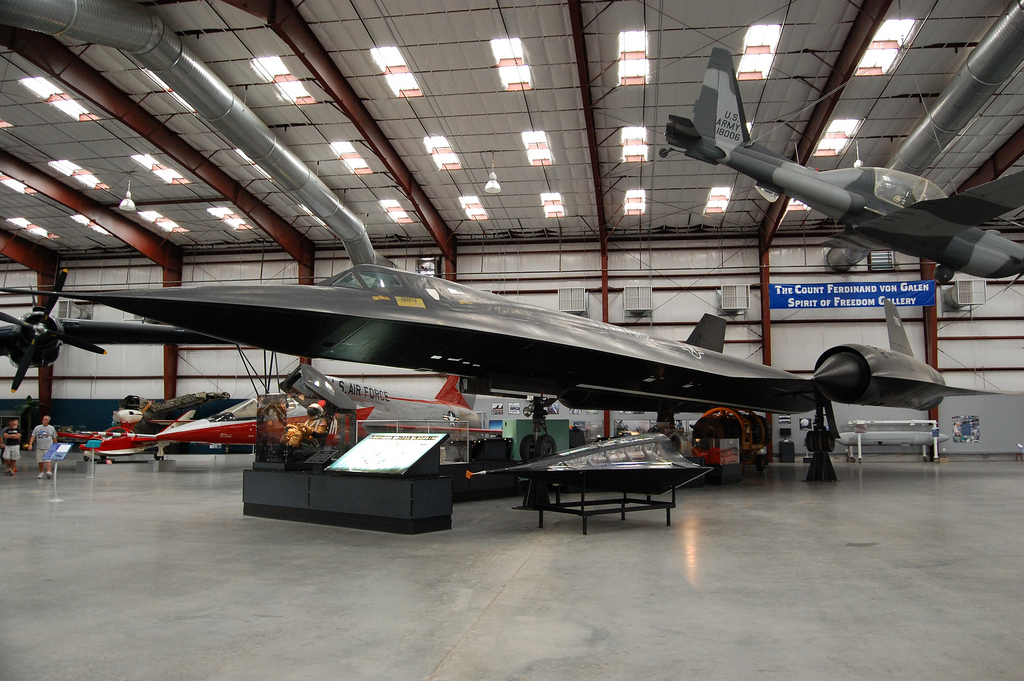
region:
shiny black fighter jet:
[60, 243, 972, 460]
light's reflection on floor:
[672, 493, 715, 579]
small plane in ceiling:
[647, 80, 993, 286]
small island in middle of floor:
[220, 415, 448, 540]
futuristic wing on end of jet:
[808, 297, 961, 434]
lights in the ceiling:
[319, 60, 724, 213]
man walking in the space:
[31, 402, 80, 478]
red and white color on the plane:
[142, 389, 346, 479]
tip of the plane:
[2, 211, 274, 401]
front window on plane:
[266, 177, 467, 356]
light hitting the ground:
[625, 487, 759, 621]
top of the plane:
[451, 260, 769, 371]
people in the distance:
[3, 385, 101, 474]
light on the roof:
[474, 97, 585, 211]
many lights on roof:
[275, 86, 688, 265]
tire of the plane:
[493, 414, 580, 479]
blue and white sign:
[729, 253, 961, 336]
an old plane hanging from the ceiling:
[661, 31, 1022, 308]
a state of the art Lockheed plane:
[15, 247, 1000, 463]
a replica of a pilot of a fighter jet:
[249, 364, 363, 478]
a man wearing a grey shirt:
[28, 408, 55, 478]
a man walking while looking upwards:
[28, 407, 60, 487]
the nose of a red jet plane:
[157, 386, 278, 444]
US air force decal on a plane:
[322, 372, 425, 420]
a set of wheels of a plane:
[517, 391, 562, 464]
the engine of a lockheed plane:
[814, 294, 991, 424]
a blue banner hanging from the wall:
[758, 275, 955, 314]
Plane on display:
[0, 256, 1016, 443]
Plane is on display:
[0, 248, 1016, 460]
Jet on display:
[0, 229, 1002, 463]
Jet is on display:
[2, 234, 1018, 470]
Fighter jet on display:
[1, 257, 1022, 453]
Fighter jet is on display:
[2, 248, 1020, 444]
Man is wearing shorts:
[32, 437, 62, 467]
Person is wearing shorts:
[1, 438, 30, 465]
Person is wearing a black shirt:
[0, 418, 29, 453]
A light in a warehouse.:
[517, 124, 555, 179]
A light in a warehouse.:
[490, 39, 530, 101]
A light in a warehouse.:
[367, 42, 431, 106]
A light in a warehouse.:
[424, 131, 457, 182]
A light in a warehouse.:
[337, 136, 358, 178]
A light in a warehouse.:
[860, 19, 909, 92]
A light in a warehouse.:
[821, 111, 866, 160]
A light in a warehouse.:
[732, 20, 774, 90]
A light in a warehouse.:
[705, 181, 732, 219]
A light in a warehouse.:
[16, 77, 93, 132]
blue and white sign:
[767, 269, 939, 317]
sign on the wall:
[761, 274, 936, 316]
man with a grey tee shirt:
[28, 410, 63, 486]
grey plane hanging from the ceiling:
[635, 42, 1021, 299]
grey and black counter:
[234, 455, 462, 547]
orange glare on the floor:
[682, 505, 705, 578]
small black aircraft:
[454, 417, 710, 510]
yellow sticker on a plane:
[388, 288, 428, 317]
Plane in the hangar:
[70, 259, 956, 512]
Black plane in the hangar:
[60, 240, 959, 519]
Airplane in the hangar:
[37, 243, 946, 544]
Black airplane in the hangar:
[78, 262, 961, 516]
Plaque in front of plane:
[321, 418, 457, 489]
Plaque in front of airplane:
[335, 432, 446, 477]